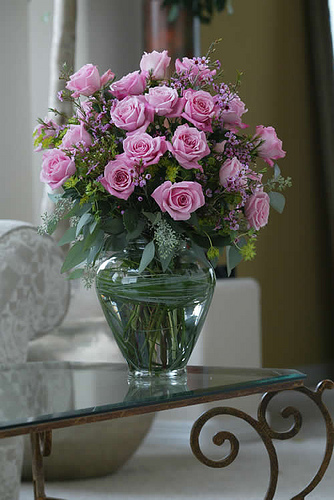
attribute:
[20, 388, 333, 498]
carpet — white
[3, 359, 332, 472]
table — clear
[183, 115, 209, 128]
buds — purple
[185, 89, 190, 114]
buds — purple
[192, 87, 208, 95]
buds — purple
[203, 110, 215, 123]
buds — purple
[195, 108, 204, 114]
buds — purple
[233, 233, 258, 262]
flowers — tiny, yellow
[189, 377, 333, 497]
leg — green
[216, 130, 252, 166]
flowers — small, purple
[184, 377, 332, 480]
scroll work — fancy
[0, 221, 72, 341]
design — white, floral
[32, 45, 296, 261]
flowers — white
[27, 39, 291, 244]
roses — pink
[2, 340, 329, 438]
table — wrought iron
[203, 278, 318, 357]
wall — white, half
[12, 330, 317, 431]
coffee table — glass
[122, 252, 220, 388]
vase — wide, clear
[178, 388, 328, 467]
designs — wrought iron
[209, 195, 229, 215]
leaves — green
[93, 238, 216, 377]
vase — wide, round, clear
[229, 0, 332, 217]
wall — tan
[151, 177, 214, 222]
rose — beautiful, pink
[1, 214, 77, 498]
designer sofa — white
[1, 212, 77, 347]
arm rest — huge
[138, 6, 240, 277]
molding — brown, column, wood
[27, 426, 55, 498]
leg — green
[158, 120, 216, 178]
flower — lavender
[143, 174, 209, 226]
flower — lavender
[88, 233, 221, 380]
vase — clear, glass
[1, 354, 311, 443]
top — glass